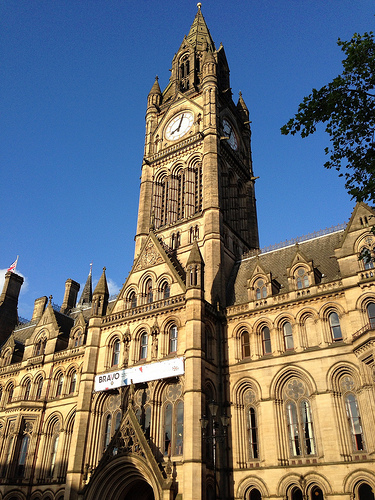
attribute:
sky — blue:
[0, 0, 375, 322]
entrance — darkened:
[80, 409, 188, 494]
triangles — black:
[137, 365, 144, 371]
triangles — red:
[120, 376, 129, 385]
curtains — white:
[263, 363, 334, 458]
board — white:
[92, 354, 185, 395]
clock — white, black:
[162, 108, 195, 140]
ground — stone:
[277, 107, 302, 146]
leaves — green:
[325, 85, 360, 146]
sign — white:
[85, 356, 197, 393]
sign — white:
[72, 350, 200, 400]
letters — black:
[88, 365, 133, 390]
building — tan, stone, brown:
[6, 31, 373, 499]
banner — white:
[82, 334, 201, 417]